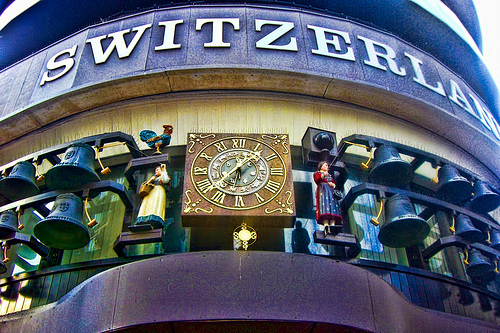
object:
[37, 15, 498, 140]
word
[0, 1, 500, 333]
building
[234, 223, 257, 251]
pendulum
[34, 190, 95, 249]
bells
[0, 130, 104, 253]
group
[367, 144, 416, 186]
bells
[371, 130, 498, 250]
group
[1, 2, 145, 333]
side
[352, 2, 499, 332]
side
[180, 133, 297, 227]
clock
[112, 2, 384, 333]
front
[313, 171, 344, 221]
dress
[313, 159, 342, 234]
statue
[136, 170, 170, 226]
dress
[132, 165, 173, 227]
figure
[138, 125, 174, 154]
rooster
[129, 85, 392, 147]
underside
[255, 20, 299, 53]
letter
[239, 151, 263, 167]
hands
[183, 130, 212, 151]
corner design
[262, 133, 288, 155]
design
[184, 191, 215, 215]
design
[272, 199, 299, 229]
design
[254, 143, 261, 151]
roman numeral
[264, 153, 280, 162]
roman numeral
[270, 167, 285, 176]
roman numeral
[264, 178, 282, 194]
roman numeral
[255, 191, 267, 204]
roman numeral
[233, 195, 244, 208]
roman numeral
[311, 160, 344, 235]
female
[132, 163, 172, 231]
female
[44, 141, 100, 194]
bell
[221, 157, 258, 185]
center